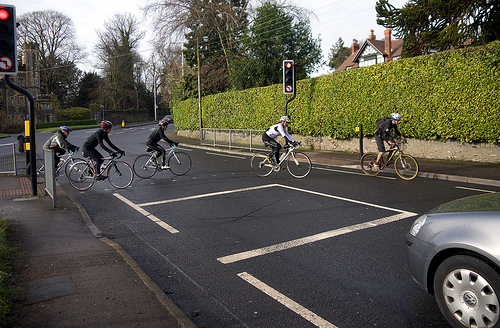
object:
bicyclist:
[261, 115, 300, 170]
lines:
[306, 165, 398, 180]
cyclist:
[42, 125, 80, 169]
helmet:
[389, 113, 401, 121]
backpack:
[375, 116, 391, 126]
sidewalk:
[160, 129, 500, 186]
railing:
[200, 127, 278, 151]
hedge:
[173, 40, 500, 143]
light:
[0, 6, 14, 57]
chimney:
[383, 29, 391, 58]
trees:
[238, 0, 325, 87]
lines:
[111, 192, 181, 234]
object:
[24, 121, 37, 137]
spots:
[172, 180, 177, 182]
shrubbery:
[171, 97, 200, 131]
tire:
[433, 249, 500, 328]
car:
[403, 191, 500, 328]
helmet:
[279, 116, 290, 123]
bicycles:
[24, 147, 90, 184]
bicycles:
[357, 136, 420, 181]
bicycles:
[131, 142, 194, 179]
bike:
[250, 144, 315, 178]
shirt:
[265, 123, 296, 143]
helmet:
[101, 120, 114, 128]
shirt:
[82, 128, 122, 153]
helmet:
[59, 125, 70, 131]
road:
[0, 120, 500, 328]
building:
[334, 25, 478, 73]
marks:
[274, 182, 419, 215]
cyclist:
[373, 112, 407, 171]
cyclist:
[145, 120, 179, 171]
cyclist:
[82, 120, 126, 182]